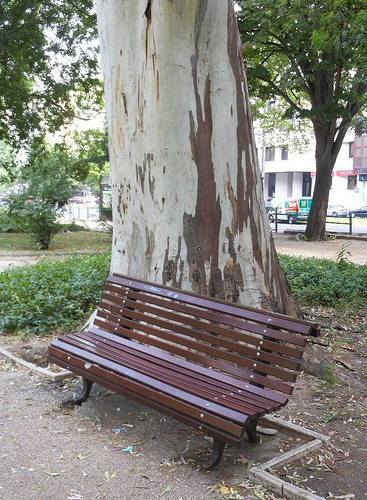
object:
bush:
[0, 129, 85, 250]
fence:
[270, 209, 352, 234]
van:
[268, 198, 308, 224]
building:
[43, 113, 118, 232]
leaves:
[304, 436, 360, 495]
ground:
[2, 302, 367, 500]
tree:
[84, 4, 303, 324]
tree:
[0, 0, 104, 234]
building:
[249, 71, 363, 227]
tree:
[246, 4, 365, 305]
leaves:
[40, 268, 66, 287]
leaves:
[313, 260, 341, 283]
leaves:
[37, 171, 58, 199]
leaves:
[313, 27, 339, 58]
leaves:
[21, 35, 45, 68]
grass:
[0, 246, 111, 343]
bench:
[46, 272, 318, 467]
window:
[302, 172, 311, 196]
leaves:
[25, 264, 86, 313]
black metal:
[63, 375, 95, 404]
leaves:
[22, 260, 61, 301]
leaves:
[230, 0, 270, 34]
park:
[0, 0, 366, 498]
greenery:
[274, 250, 367, 309]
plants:
[335, 240, 355, 274]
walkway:
[3, 335, 265, 497]